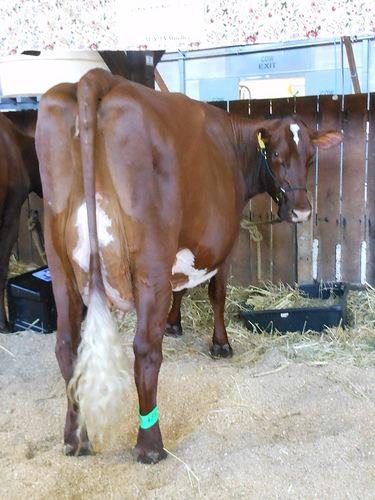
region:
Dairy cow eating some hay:
[27, 64, 343, 469]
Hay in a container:
[240, 273, 353, 330]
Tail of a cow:
[64, 73, 146, 454]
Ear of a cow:
[306, 124, 346, 154]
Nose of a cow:
[271, 199, 317, 225]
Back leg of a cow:
[124, 261, 170, 465]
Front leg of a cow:
[199, 266, 237, 365]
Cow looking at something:
[248, 108, 348, 240]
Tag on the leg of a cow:
[127, 400, 169, 468]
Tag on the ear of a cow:
[248, 125, 275, 152]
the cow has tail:
[38, 119, 201, 361]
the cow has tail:
[68, 101, 314, 315]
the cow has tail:
[20, 5, 276, 263]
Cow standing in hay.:
[32, 67, 370, 492]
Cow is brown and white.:
[22, 66, 340, 471]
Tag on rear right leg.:
[30, 63, 338, 480]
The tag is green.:
[23, 60, 197, 470]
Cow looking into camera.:
[23, 63, 372, 496]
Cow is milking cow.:
[7, 57, 350, 477]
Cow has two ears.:
[248, 111, 350, 239]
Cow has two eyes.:
[245, 108, 351, 238]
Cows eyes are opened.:
[251, 95, 341, 232]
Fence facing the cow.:
[1, 90, 374, 302]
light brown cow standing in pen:
[20, 56, 345, 482]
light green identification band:
[129, 397, 167, 436]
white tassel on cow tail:
[70, 253, 139, 457]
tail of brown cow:
[66, 61, 140, 440]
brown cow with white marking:
[242, 91, 349, 253]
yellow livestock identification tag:
[250, 116, 271, 157]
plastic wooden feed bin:
[229, 265, 350, 347]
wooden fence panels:
[317, 95, 373, 287]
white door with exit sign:
[250, 53, 307, 101]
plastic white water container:
[6, 257, 67, 338]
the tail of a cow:
[71, 76, 132, 462]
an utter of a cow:
[107, 267, 134, 331]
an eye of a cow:
[270, 147, 282, 162]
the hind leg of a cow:
[128, 226, 170, 468]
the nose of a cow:
[282, 200, 314, 228]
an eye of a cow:
[314, 124, 346, 154]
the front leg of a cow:
[203, 268, 244, 356]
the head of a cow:
[255, 113, 347, 225]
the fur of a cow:
[181, 131, 212, 186]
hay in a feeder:
[248, 281, 328, 323]